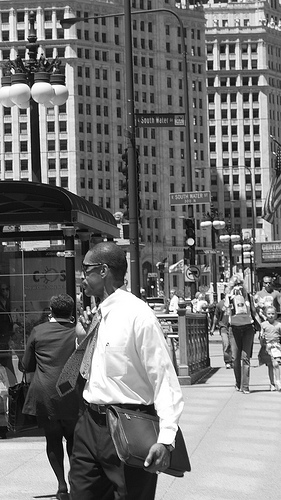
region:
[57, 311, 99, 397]
tie of the man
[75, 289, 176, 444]
white t-shirt in man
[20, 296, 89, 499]
woman from behind walking in the street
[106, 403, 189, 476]
black portfolio on left hand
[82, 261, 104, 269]
black glasses on head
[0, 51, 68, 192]
light post with four white light bulbs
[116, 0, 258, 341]
large black poles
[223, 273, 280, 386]
woman walking with a bag in her hand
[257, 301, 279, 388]
little girl in dress walking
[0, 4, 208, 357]
big window with a bunch of windows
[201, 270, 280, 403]
people walking on sidewalk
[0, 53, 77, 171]
big buildings in a city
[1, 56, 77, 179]
a pole with six lights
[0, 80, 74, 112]
lights are white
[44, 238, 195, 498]
a man is turned back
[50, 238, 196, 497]
man wears a coat on right hand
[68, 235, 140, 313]
man wears glasses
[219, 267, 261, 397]
a blond woman holds a paper bag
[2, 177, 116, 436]
a bus stop on side the street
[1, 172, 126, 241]
roof of bus stop is black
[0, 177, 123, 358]
Bus stop on sidewalk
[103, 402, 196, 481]
Briefcase man is carrying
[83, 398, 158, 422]
Belt man is wearing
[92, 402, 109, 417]
Belt buckle on belt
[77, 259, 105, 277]
Glasses on man's face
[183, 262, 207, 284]
Sign with truck on it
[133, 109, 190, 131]
Street sign on pole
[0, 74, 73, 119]
Light bulbs on light pole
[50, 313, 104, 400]
Tie man is wearing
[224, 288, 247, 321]
Bag woman is carrying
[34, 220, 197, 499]
a man with a tie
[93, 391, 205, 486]
breifcase held in a hand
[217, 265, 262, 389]
a woman with a shopping bag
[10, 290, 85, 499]
a woman with a black handbag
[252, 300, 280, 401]
a little girl walking with her mother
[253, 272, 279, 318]
a man walking behind mother and daughter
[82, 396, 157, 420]
a belt worn by a man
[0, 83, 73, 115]
four round white light covers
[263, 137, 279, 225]
an american flag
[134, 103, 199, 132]
a sign with the street name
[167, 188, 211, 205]
a street sign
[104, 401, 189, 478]
a thick zipper case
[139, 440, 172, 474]
a man's left hand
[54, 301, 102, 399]
a man's dress tie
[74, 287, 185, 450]
a button down dress shirt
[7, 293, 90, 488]
a woman dressed in a dress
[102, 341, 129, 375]
a front shirt pocket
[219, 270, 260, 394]
a lady walking on a sidewalk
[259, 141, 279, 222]
an american flag flying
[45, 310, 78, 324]
a woman's hoop earings